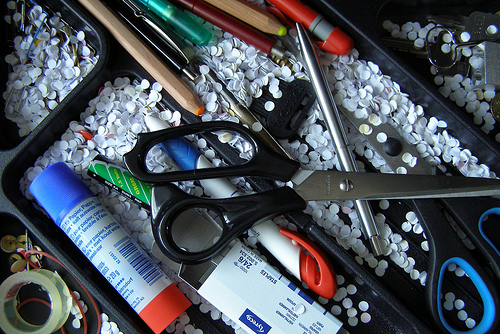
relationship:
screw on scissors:
[335, 174, 353, 191] [121, 124, 499, 256]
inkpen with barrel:
[140, 109, 336, 297] [232, 190, 305, 280]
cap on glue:
[29, 161, 100, 229] [26, 159, 192, 332]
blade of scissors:
[343, 165, 498, 207] [121, 124, 499, 256]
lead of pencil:
[276, 27, 286, 34] [211, 0, 287, 47]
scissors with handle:
[121, 121, 499, 256] [109, 118, 312, 268]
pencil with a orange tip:
[77, 0, 209, 117] [193, 103, 206, 118]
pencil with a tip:
[77, 0, 209, 117] [195, 104, 205, 118]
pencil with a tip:
[185, 0, 286, 37] [271, 22, 291, 38]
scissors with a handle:
[340, 104, 499, 332] [435, 194, 499, 276]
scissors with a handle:
[340, 104, 499, 332] [408, 200, 499, 330]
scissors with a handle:
[340, 104, 499, 332] [153, 186, 308, 264]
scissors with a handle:
[340, 104, 499, 332] [123, 122, 301, 187]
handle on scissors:
[109, 118, 312, 268] [96, 111, 496, 267]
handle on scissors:
[442, 235, 497, 302] [312, 90, 497, 332]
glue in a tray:
[26, 159, 192, 332] [1, 3, 498, 328]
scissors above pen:
[121, 121, 499, 256] [286, 26, 394, 260]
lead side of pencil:
[193, 105, 205, 114] [77, 0, 209, 117]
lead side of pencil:
[276, 27, 286, 34] [200, 0, 286, 35]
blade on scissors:
[343, 165, 498, 207] [121, 124, 499, 256]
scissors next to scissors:
[121, 124, 499, 256] [340, 104, 499, 332]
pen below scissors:
[289, 19, 386, 264] [121, 124, 499, 256]